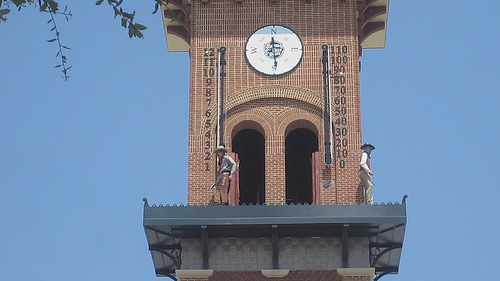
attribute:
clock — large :
[237, 17, 327, 98]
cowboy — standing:
[357, 139, 373, 206]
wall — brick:
[198, 28, 308, 75]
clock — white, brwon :
[240, 21, 302, 79]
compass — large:
[242, 19, 307, 81]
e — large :
[288, 46, 298, 53]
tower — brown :
[147, 4, 407, 279]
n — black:
[265, 26, 280, 36]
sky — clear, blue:
[2, 0, 498, 279]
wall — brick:
[323, 37, 355, 57]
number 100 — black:
[329, 52, 349, 64]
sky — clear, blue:
[6, 27, 183, 207]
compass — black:
[244, 22, 304, 77]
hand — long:
[270, 36, 277, 68]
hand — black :
[271, 37, 278, 56]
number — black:
[250, 32, 299, 74]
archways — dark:
[226, 114, 324, 204]